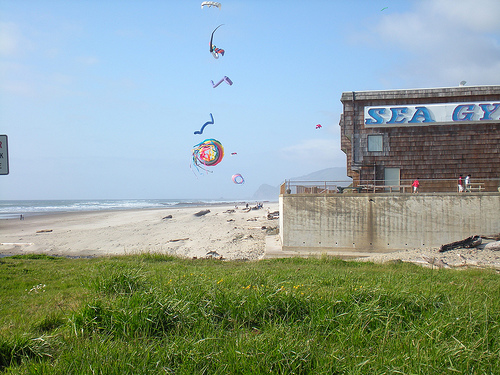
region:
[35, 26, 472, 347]
This is along a beach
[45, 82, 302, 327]
this is a along a coast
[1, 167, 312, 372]
this is a beside an ocean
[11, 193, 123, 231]
this is an ocean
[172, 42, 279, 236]
these are kites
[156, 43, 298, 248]
the kites are multicolored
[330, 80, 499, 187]
this is a shop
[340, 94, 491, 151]
this says Sea Gy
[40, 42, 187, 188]
the sky is partly cloudy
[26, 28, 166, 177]
the sky is blue and white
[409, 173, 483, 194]
three people watching kites from their motel deck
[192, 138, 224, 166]
rainbow bol kite in the air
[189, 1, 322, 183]
kites flying above a beach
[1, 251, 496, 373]
grassy strip of land next to a beach motel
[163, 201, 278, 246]
driftwood on the beach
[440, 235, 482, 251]
charred driftwood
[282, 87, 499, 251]
motel right on the beach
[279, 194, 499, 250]
concrete protective breakwater wall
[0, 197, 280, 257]
beach with breaking waves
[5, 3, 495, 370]
Flying kites on the beach behind a beach motel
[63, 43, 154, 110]
sky above the land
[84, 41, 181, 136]
blue sky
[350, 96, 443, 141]
the word "sea" in blue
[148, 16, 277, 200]
kites in the air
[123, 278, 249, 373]
grass in the foreground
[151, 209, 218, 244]
sand on the ground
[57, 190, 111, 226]
white wave in the ocean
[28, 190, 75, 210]
ocean in the distance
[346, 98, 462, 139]
sign on a building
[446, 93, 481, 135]
the letter G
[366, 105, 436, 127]
The word SEA on the side of a building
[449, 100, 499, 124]
A large G Y on a sign on the building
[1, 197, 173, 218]
Grey and white ocean past the beach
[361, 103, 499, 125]
A white sign with blue writing that says SEA GY.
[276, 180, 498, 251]
A dirty white fence all around the building.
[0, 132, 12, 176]
Barely visible black and white sign.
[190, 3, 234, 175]
A long kite in the sky.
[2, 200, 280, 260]
All of the tan colored sand.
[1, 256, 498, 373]
A green area of grass.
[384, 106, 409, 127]
The blue letter E in SEA.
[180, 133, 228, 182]
kite in the sky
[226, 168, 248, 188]
kite in the sky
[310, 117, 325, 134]
kite in the sky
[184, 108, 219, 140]
kite in the sky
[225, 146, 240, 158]
kite in the sky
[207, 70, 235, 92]
kite in the sky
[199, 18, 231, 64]
kite in the sky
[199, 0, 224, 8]
kite in the sky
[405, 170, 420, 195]
person near a building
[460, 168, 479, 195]
person near a building